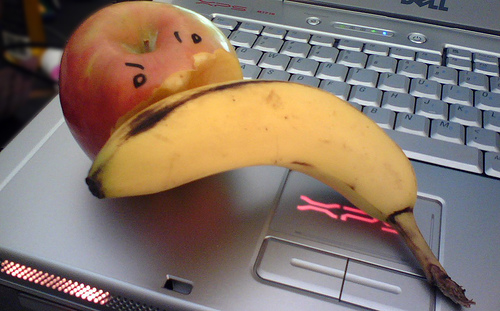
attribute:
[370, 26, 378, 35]
light — green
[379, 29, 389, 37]
light — blue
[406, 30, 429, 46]
button — power button, silver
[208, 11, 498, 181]
keyboard — gray computer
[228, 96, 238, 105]
spot — brown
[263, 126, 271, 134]
spot — brown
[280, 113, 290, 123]
spot — brown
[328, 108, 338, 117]
spot — brown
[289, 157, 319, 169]
spot — brown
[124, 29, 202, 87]
marks — black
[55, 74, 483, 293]
banana — yellow, bruised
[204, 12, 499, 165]
grey keyboard — keys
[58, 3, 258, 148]
apple — red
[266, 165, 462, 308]
touch pad — laptop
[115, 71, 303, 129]
banana marks — black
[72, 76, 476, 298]
banana over laptop — trackpad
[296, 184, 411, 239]
xps on trackpad — lighted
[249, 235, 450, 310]
mouse buttons — gray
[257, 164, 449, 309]
touch pad — gray